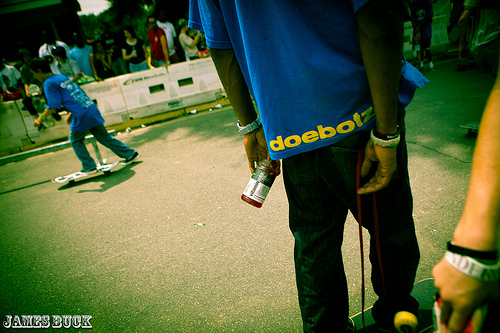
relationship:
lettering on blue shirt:
[264, 107, 378, 152] [187, 0, 429, 160]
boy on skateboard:
[31, 60, 139, 175] [49, 157, 121, 188]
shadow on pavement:
[72, 157, 140, 193] [3, 105, 301, 332]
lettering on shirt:
[60, 79, 93, 110] [38, 72, 108, 127]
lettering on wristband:
[445, 250, 498, 282] [440, 242, 498, 281]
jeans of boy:
[70, 110, 136, 175] [31, 60, 139, 175]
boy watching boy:
[31, 60, 139, 175] [31, 60, 139, 175]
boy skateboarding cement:
[31, 60, 139, 175] [8, 139, 289, 310]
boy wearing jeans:
[31, 60, 139, 175] [256, 140, 423, 285]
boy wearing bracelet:
[187, 1, 427, 333] [236, 117, 262, 134]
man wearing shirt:
[145, 23, 170, 75] [147, 31, 171, 63]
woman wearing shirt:
[122, 27, 146, 74] [121, 38, 145, 59]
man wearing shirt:
[66, 31, 101, 85] [68, 45, 97, 78]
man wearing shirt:
[154, 12, 178, 57] [154, 20, 174, 56]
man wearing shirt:
[39, 32, 69, 64] [37, 40, 67, 70]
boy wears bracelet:
[187, 1, 427, 333] [234, 117, 266, 135]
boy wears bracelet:
[187, 1, 427, 333] [367, 129, 403, 146]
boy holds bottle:
[23, 60, 146, 173] [235, 147, 294, 209]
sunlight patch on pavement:
[31, 125, 471, 328] [3, 44, 497, 330]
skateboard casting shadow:
[48, 159, 118, 189] [72, 157, 142, 195]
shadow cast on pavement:
[72, 157, 142, 195] [3, 44, 497, 330]